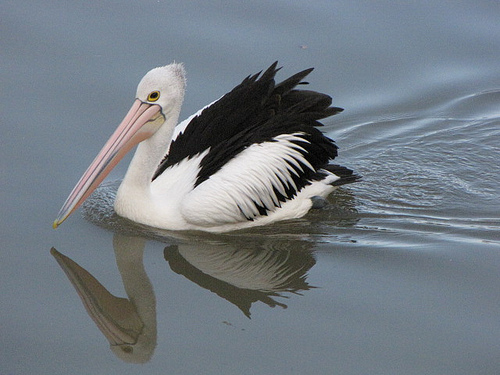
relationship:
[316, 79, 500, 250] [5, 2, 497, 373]
ripple in water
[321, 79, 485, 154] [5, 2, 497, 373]
ripple in water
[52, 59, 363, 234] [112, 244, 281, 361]
bird on water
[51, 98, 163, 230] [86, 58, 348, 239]
beak of a bird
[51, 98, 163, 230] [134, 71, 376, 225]
beak of a bird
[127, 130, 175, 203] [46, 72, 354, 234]
neck of a bird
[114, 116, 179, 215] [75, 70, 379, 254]
neck of a bird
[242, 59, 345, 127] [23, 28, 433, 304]
bird tail of a bird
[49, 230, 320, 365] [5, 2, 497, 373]
reflection on water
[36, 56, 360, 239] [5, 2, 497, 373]
bird in water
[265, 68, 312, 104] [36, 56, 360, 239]
black feathers of bird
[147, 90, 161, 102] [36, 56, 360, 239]
eye attached to bird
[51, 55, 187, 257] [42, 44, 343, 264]
head attached to bird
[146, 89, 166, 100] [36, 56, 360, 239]
eye attached to bird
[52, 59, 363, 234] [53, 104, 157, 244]
bird has beak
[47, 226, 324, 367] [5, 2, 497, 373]
reflection in water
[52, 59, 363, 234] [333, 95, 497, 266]
bird making waves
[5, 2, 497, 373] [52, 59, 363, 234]
water behind bird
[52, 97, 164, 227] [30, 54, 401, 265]
beak on bird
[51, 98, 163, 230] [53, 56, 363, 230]
beak on bird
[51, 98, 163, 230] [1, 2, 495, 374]
beak on bird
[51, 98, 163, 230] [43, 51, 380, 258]
beak on bird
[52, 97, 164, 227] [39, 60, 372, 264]
beak on bird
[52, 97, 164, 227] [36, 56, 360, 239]
beak on bird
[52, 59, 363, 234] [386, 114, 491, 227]
bird leaves wave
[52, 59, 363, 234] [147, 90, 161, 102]
bird has eye